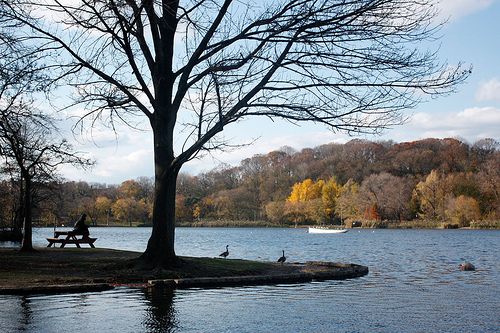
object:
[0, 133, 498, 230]
background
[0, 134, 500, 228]
forest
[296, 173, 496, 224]
hill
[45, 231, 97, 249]
table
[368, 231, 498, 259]
water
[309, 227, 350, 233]
boat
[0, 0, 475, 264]
tree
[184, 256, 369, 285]
peninsula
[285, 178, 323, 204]
tree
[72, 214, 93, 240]
person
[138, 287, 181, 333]
reflection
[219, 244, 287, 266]
birds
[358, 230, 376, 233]
birds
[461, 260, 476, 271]
object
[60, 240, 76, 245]
wood